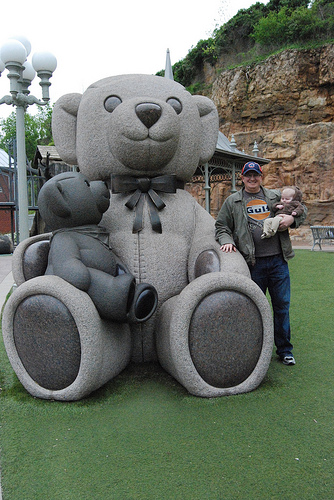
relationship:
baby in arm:
[253, 181, 307, 243] [277, 202, 318, 234]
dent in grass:
[8, 375, 135, 414] [11, 407, 333, 495]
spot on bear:
[108, 263, 130, 278] [37, 170, 162, 322]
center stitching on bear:
[127, 208, 152, 365] [3, 63, 282, 413]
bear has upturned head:
[22, 162, 161, 322] [23, 165, 114, 232]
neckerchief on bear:
[45, 225, 119, 257] [22, 162, 161, 322]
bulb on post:
[26, 45, 64, 78] [6, 46, 58, 253]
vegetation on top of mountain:
[163, 2, 332, 88] [174, 49, 331, 250]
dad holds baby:
[205, 159, 323, 377] [253, 181, 307, 243]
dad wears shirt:
[205, 159, 323, 377] [237, 188, 289, 265]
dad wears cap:
[205, 159, 323, 377] [238, 158, 266, 179]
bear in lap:
[22, 162, 161, 322] [13, 257, 274, 410]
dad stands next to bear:
[205, 159, 323, 377] [3, 63, 282, 413]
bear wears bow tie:
[3, 63, 282, 413] [95, 164, 191, 239]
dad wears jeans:
[205, 159, 323, 377] [241, 256, 304, 363]